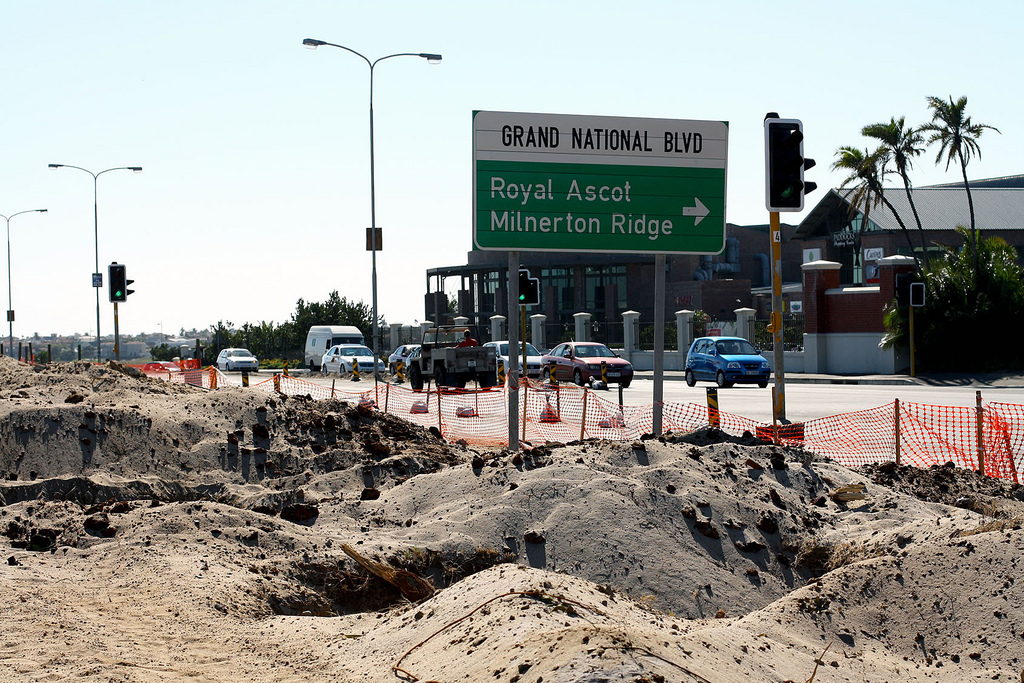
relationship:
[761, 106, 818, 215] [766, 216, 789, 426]
traffic light on pole